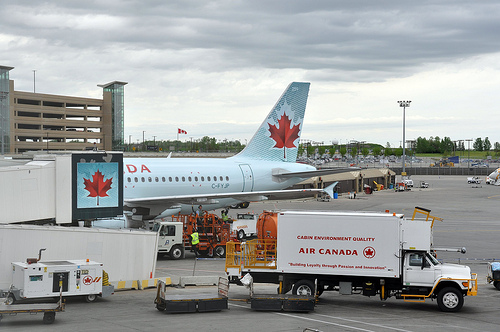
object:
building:
[0, 66, 129, 156]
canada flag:
[178, 128, 187, 133]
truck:
[277, 210, 476, 311]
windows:
[127, 177, 131, 182]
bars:
[427, 278, 442, 297]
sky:
[0, 0, 499, 140]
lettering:
[297, 236, 375, 242]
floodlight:
[397, 101, 411, 172]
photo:
[0, 0, 499, 332]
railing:
[227, 239, 276, 245]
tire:
[436, 287, 464, 312]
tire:
[292, 279, 314, 295]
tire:
[170, 246, 183, 260]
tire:
[213, 245, 226, 257]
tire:
[237, 229, 244, 239]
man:
[188, 230, 199, 260]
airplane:
[122, 83, 365, 221]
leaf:
[268, 110, 301, 158]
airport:
[0, 137, 500, 330]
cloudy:
[0, 0, 499, 84]